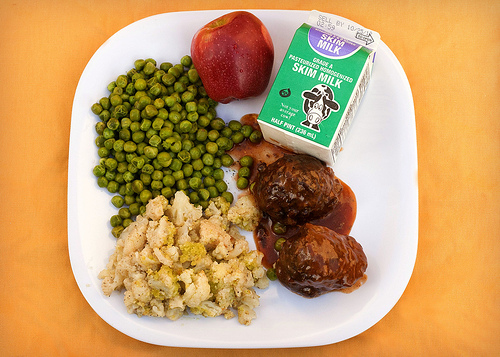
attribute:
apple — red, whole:
[194, 11, 273, 106]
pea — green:
[185, 56, 192, 67]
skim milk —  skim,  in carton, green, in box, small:
[259, 9, 382, 158]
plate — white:
[65, 10, 424, 351]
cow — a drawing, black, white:
[297, 82, 342, 133]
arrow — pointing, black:
[351, 32, 375, 47]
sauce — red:
[321, 206, 355, 229]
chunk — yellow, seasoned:
[99, 191, 262, 325]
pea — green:
[138, 62, 157, 75]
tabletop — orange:
[5, 14, 76, 89]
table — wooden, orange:
[2, 4, 75, 63]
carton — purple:
[306, 25, 367, 61]